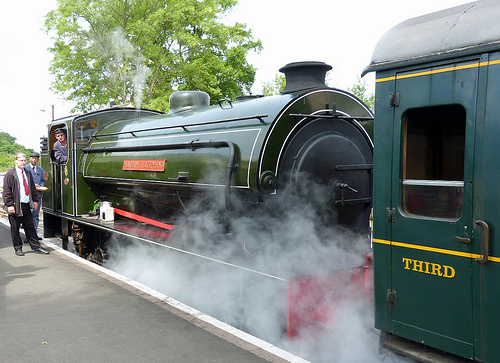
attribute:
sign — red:
[121, 157, 164, 169]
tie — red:
[16, 172, 38, 200]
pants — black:
[9, 205, 39, 248]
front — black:
[234, 76, 354, 261]